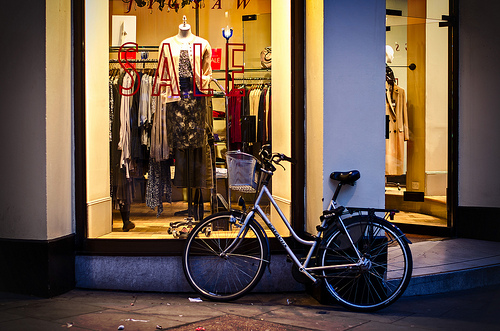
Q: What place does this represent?
A: It represents the store.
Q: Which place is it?
A: It is a store.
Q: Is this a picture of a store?
A: Yes, it is showing a store.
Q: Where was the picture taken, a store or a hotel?
A: It was taken at a store.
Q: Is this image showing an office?
A: No, the picture is showing a store.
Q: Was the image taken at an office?
A: No, the picture was taken in a store.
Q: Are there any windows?
A: Yes, there is a window.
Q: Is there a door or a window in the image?
A: Yes, there is a window.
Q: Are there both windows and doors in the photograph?
A: Yes, there are both a window and a door.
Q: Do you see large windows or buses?
A: Yes, there is a large window.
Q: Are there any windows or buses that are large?
A: Yes, the window is large.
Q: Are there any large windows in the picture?
A: Yes, there is a large window.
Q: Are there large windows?
A: Yes, there is a large window.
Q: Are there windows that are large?
A: Yes, there is a window that is large.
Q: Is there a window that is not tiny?
A: Yes, there is a large window.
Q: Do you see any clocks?
A: No, there are no clocks.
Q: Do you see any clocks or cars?
A: No, there are no clocks or cars.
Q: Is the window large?
A: Yes, the window is large.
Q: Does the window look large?
A: Yes, the window is large.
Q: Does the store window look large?
A: Yes, the window is large.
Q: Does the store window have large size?
A: Yes, the window is large.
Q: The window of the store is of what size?
A: The window is large.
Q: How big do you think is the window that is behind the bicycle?
A: The window is large.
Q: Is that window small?
A: No, the window is large.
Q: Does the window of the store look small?
A: No, the window is large.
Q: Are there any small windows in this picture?
A: No, there is a window but it is large.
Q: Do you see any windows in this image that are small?
A: No, there is a window but it is large.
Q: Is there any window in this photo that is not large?
A: No, there is a window but it is large.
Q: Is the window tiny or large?
A: The window is large.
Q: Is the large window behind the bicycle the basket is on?
A: Yes, the window is behind the bicycle.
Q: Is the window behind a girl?
A: No, the window is behind the bicycle.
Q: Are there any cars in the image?
A: No, there are no cars.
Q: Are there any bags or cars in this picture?
A: No, there are no cars or bags.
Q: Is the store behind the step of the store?
A: Yes, the store is behind the step.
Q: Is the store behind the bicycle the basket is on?
A: Yes, the store is behind the bicycle.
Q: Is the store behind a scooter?
A: No, the store is behind the bicycle.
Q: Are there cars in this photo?
A: No, there are no cars.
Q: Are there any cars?
A: No, there are no cars.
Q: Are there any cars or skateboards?
A: No, there are no cars or skateboards.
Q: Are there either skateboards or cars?
A: No, there are no cars or skateboards.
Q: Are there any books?
A: No, there are no books.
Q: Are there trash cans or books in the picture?
A: No, there are no books or trash cans.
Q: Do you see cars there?
A: No, there are no cars.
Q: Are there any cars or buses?
A: No, there are no cars or buses.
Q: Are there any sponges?
A: No, there are no sponges.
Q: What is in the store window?
A: The mannequin is in the window.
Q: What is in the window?
A: The mannequin is in the window.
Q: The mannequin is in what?
A: The mannequin is in the window.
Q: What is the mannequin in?
A: The mannequin is in the window.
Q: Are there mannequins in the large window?
A: Yes, there is a mannequin in the window.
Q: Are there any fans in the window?
A: No, there is a mannequin in the window.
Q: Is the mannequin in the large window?
A: Yes, the mannequin is in the window.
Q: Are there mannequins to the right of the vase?
A: Yes, there is a mannequin to the right of the vase.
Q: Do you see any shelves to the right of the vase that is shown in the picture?
A: No, there is a mannequin to the right of the vase.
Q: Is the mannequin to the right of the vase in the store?
A: Yes, the mannequin is to the right of the vase.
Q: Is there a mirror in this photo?
A: No, there are no mirrors.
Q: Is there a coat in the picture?
A: Yes, there is a coat.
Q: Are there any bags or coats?
A: Yes, there is a coat.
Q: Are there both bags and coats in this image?
A: No, there is a coat but no bags.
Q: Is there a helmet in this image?
A: No, there are no helmets.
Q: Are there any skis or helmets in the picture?
A: No, there are no helmets or skis.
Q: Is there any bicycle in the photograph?
A: Yes, there is a bicycle.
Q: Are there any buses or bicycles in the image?
A: Yes, there is a bicycle.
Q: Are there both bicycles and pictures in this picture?
A: No, there is a bicycle but no pictures.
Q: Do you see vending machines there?
A: No, there are no vending machines.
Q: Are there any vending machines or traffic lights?
A: No, there are no vending machines or traffic lights.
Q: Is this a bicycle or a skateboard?
A: This is a bicycle.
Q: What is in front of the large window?
A: The bicycle is in front of the window.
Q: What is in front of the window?
A: The bicycle is in front of the window.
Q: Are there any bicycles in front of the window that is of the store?
A: Yes, there is a bicycle in front of the window.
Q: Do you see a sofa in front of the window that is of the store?
A: No, there is a bicycle in front of the window.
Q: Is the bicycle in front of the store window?
A: Yes, the bicycle is in front of the window.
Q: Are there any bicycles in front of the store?
A: Yes, there is a bicycle in front of the store.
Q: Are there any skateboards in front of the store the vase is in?
A: No, there is a bicycle in front of the store.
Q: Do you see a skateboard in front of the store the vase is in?
A: No, there is a bicycle in front of the store.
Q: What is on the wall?
A: The bicycle is on the wall.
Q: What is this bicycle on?
A: The bicycle is on the wall.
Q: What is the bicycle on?
A: The bicycle is on the wall.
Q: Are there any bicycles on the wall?
A: Yes, there is a bicycle on the wall.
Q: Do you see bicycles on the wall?
A: Yes, there is a bicycle on the wall.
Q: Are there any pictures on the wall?
A: No, there is a bicycle on the wall.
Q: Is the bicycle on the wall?
A: Yes, the bicycle is on the wall.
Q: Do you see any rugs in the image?
A: No, there are no rugs.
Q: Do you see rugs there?
A: No, there are no rugs.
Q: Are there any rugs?
A: No, there are no rugs.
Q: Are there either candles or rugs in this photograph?
A: No, there are no rugs or candles.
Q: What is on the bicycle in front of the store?
A: The basket is on the bicycle.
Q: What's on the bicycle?
A: The basket is on the bicycle.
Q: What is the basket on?
A: The basket is on the bicycle.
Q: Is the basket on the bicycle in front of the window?
A: Yes, the basket is on the bicycle.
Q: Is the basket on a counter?
A: No, the basket is on the bicycle.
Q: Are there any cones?
A: No, there are no cones.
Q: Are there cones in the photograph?
A: No, there are no cones.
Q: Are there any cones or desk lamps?
A: No, there are no cones or desk lamps.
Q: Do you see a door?
A: Yes, there is a door.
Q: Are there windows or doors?
A: Yes, there is a door.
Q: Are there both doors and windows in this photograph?
A: Yes, there are both a door and a window.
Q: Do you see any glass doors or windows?
A: Yes, there is a glass door.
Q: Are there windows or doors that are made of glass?
A: Yes, the door is made of glass.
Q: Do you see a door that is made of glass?
A: Yes, there is a door that is made of glass.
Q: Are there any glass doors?
A: Yes, there is a door that is made of glass.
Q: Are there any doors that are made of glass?
A: Yes, there is a door that is made of glass.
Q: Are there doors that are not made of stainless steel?
A: Yes, there is a door that is made of glass.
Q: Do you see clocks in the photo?
A: No, there are no clocks.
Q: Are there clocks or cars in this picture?
A: No, there are no clocks or cars.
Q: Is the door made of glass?
A: Yes, the door is made of glass.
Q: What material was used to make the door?
A: The door is made of glass.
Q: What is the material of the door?
A: The door is made of glass.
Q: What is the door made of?
A: The door is made of glass.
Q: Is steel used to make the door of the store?
A: No, the door is made of glass.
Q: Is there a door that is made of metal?
A: No, there is a door but it is made of glass.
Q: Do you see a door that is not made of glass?
A: No, there is a door but it is made of glass.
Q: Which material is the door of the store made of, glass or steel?
A: The door is made of glass.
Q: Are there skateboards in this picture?
A: No, there are no skateboards.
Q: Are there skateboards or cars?
A: No, there are no skateboards or cars.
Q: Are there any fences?
A: No, there are no fences.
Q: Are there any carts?
A: No, there are no carts.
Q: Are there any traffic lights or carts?
A: No, there are no carts or traffic lights.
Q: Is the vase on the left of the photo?
A: Yes, the vase is on the left of the image.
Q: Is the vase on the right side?
A: No, the vase is on the left of the image.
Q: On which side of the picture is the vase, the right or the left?
A: The vase is on the left of the image.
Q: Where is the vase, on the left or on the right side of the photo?
A: The vase is on the left of the image.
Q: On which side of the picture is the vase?
A: The vase is on the left of the image.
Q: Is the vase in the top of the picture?
A: Yes, the vase is in the top of the image.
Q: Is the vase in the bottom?
A: No, the vase is in the top of the image.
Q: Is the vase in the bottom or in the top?
A: The vase is in the top of the image.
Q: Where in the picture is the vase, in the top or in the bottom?
A: The vase is in the top of the image.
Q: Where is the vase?
A: The vase is in the store.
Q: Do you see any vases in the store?
A: Yes, there is a vase in the store.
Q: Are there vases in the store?
A: Yes, there is a vase in the store.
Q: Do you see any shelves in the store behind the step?
A: No, there is a vase in the store.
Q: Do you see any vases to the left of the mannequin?
A: Yes, there is a vase to the left of the mannequin.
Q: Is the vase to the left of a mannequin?
A: Yes, the vase is to the left of a mannequin.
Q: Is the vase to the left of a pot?
A: No, the vase is to the left of a mannequin.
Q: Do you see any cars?
A: No, there are no cars.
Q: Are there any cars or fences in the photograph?
A: No, there are no cars or fences.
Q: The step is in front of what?
A: The step is in front of the store.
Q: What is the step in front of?
A: The step is in front of the store.